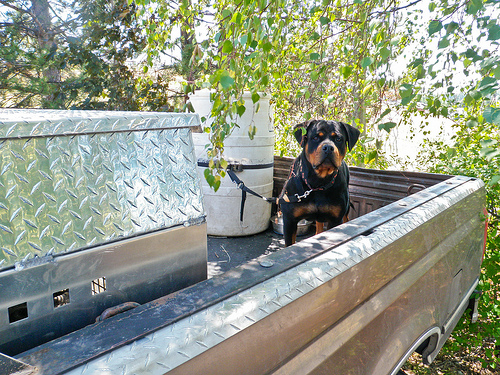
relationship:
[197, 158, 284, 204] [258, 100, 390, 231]
leash attached to dog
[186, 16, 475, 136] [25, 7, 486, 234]
leaves on trees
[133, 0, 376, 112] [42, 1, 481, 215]
leaves on tree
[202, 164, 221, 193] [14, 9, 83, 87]
leaves on trees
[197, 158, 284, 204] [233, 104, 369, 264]
leash attatched to dog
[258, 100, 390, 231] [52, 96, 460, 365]
dog in back of truck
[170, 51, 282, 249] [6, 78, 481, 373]
barrel in back of truck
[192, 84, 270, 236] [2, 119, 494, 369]
white barrel in back of truck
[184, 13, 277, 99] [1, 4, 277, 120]
leaves attached to tree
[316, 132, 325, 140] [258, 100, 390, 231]
spot on dog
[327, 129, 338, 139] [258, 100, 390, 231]
spot on dog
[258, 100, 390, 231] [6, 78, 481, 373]
dog on truck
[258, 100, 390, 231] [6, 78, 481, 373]
dog in a truck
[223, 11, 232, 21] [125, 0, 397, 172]
leaves in tree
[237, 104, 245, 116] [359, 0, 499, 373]
leaves in tree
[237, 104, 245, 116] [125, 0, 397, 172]
leaves in tree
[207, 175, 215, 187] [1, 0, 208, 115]
leaves in tree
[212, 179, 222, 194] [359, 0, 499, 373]
leaves in tree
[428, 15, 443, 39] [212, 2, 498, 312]
leaf on tree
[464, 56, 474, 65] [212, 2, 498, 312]
leaf on tree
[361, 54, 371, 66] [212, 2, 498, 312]
leaf on tree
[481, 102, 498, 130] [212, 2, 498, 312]
leaf on tree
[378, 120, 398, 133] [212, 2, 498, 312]
leaf on tree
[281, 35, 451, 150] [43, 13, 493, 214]
leaves on trees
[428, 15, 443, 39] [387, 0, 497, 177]
leaf on tree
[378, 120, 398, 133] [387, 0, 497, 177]
leaf on tree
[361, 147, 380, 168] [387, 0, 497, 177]
leaf on tree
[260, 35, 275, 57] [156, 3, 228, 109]
leaf on tree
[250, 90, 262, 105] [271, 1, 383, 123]
leaf on tree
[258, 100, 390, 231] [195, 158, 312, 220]
dog has leash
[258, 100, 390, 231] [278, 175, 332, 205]
dog wears collar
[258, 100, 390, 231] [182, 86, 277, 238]
dog tied to barrel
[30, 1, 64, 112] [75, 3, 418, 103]
tree trunk with surrounding branches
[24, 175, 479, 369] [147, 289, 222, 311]
metal strip with rusted spots